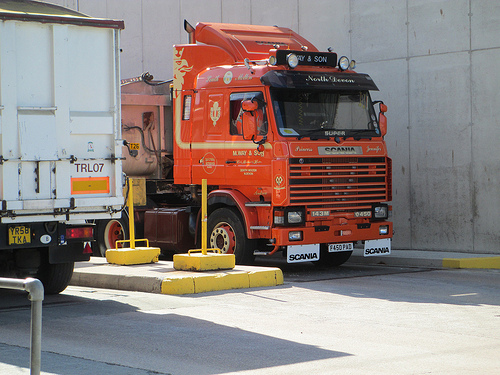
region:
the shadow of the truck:
[10, 292, 350, 373]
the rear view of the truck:
[0, 22, 115, 277]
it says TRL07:
[74, 160, 104, 177]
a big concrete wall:
[412, 34, 497, 234]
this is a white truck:
[0, 14, 122, 223]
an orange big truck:
[182, 34, 391, 257]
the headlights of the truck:
[279, 205, 389, 240]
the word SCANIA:
[290, 251, 316, 259]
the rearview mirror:
[241, 100, 256, 143]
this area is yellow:
[170, 271, 278, 290]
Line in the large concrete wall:
[465, 22, 475, 101]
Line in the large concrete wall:
[397, 19, 418, 108]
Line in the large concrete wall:
[399, 45, 478, 68]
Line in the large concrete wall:
[457, 63, 481, 233]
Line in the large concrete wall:
[398, 67, 424, 218]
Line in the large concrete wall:
[357, 52, 397, 64]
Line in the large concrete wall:
[336, 3, 368, 58]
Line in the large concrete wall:
[133, 8, 161, 70]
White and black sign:
[283, 248, 326, 265]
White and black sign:
[362, 236, 397, 262]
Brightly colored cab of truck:
[173, 18, 405, 268]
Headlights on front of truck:
[272, 203, 394, 225]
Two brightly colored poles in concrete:
[107, 173, 240, 273]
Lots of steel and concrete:
[2, 0, 496, 373]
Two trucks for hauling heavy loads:
[3, 0, 400, 294]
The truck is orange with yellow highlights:
[171, 19, 399, 256]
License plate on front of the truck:
[326, 242, 356, 252]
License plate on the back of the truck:
[6, 223, 35, 246]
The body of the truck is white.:
[1, 1, 127, 223]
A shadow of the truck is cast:
[3, 271, 362, 373]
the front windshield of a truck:
[267, 85, 377, 140]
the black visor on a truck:
[261, 70, 380, 93]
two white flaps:
[289, 238, 394, 264]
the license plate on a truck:
[327, 242, 352, 251]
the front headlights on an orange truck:
[279, 206, 386, 224]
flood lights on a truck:
[285, 52, 350, 72]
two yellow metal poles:
[124, 174, 212, 249]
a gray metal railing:
[0, 276, 43, 373]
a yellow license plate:
[8, 225, 30, 242]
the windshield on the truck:
[273, 89, 375, 130]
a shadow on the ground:
[108, 319, 240, 365]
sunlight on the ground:
[342, 312, 422, 347]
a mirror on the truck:
[238, 96, 260, 112]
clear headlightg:
[286, 55, 300, 66]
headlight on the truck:
[283, 207, 304, 222]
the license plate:
[8, 228, 35, 242]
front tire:
[212, 205, 238, 250]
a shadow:
[387, 271, 437, 298]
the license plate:
[328, 245, 354, 252]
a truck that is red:
[148, 42, 406, 276]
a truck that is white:
[0, 9, 123, 306]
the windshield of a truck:
[255, 82, 395, 142]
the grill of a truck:
[289, 140, 386, 233]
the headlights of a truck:
[275, 204, 391, 223]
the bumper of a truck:
[267, 226, 386, 247]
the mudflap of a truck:
[270, 238, 323, 268]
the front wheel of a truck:
[200, 209, 255, 261]